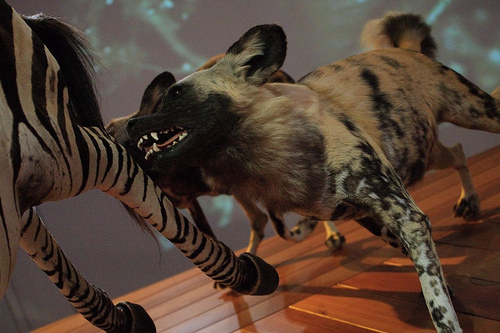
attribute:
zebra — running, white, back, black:
[8, 18, 139, 247]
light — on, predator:
[92, 6, 485, 299]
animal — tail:
[55, 21, 106, 122]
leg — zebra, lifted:
[90, 141, 193, 245]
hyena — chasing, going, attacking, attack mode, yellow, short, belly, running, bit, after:
[202, 38, 422, 218]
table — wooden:
[316, 259, 389, 332]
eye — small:
[171, 82, 201, 100]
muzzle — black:
[128, 49, 167, 99]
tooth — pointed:
[144, 120, 183, 148]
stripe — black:
[27, 59, 79, 134]